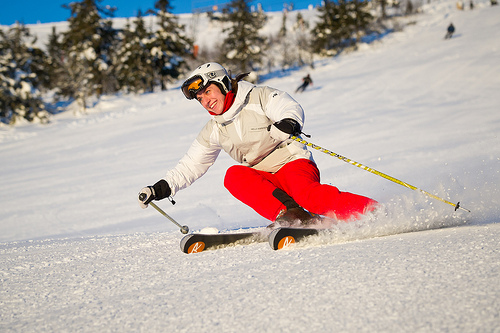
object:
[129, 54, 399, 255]
skier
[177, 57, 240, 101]
helmet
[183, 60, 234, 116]
head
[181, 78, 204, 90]
glass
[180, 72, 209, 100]
goggles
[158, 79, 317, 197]
coat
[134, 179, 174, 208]
glove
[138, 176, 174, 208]
hand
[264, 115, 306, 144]
glove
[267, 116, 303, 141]
hand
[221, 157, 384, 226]
pants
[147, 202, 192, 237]
pole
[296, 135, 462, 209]
pole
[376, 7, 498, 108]
hill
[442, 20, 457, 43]
skier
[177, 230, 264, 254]
ski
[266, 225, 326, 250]
ski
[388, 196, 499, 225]
snow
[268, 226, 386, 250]
bottom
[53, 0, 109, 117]
trees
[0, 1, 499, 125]
background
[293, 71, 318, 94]
people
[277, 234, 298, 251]
emblem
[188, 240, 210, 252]
emblem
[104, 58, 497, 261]
skiing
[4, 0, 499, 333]
day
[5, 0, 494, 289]
air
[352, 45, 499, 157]
slope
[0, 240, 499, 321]
ground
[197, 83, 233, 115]
face